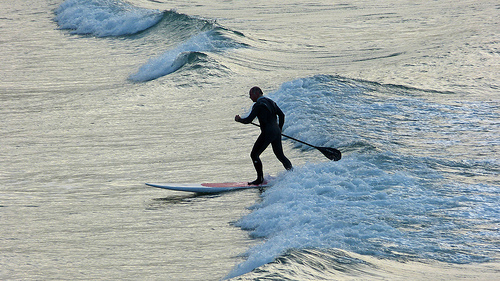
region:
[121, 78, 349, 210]
person standing on a board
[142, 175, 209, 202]
board is curved at the top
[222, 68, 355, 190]
person holding a paddle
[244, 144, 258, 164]
knee is bent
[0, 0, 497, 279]
body of water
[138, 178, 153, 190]
pointy tip of the board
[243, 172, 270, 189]
foot planted on the board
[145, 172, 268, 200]
board sticking out of the water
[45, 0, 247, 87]
small wave in the water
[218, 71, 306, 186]
this is a person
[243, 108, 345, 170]
this is a a stick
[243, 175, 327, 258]
this is a wave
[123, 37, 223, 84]
this is a wave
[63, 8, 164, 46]
this is a wave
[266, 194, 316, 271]
this is a wave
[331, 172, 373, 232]
this is a wave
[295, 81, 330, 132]
this is a wave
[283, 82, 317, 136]
this is a wave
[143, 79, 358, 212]
This is a person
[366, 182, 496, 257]
Section of a lake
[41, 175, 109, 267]
Section of a lake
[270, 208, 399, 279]
Section of a lake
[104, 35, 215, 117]
Section of a lake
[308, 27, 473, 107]
Section of a lake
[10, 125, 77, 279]
Section of a lake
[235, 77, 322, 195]
A man in the sea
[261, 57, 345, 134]
A white water ocean wave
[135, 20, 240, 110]
A white water ocean wave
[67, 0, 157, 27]
A white water ocean wave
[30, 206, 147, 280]
A grey water surface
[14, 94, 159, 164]
A grey water surface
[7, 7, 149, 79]
A grey water surface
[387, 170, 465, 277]
A grey water surface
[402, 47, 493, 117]
A grey water surface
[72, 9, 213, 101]
ocean waves are breaking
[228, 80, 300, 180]
man is standing on a surfboard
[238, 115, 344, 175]
man has a paddle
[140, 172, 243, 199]
surfboard is in the water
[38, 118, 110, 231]
water is calm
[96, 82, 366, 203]
man is paddling on the surfboard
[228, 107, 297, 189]
man is wearing a wet suit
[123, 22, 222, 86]
waves in the ocean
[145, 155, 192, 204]
surfboard is sticking out of the water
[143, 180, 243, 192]
red and white surfboard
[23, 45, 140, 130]
Large body of water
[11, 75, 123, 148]
Large body of water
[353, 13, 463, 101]
Large body of water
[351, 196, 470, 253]
Large body of water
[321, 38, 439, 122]
Large body of water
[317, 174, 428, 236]
Large body of water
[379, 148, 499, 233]
Large body of water